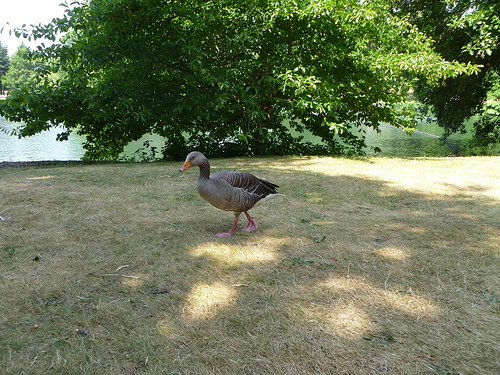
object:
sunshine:
[236, 155, 500, 201]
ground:
[0, 155, 499, 375]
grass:
[138, 218, 500, 375]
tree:
[0, 0, 499, 163]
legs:
[229, 215, 239, 233]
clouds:
[0, 4, 57, 21]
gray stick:
[379, 124, 456, 154]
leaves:
[310, 235, 327, 244]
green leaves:
[66, 0, 500, 163]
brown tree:
[0, 1, 485, 154]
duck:
[180, 151, 281, 238]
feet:
[215, 215, 238, 238]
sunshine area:
[281, 5, 500, 157]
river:
[0, 109, 500, 162]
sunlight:
[0, 104, 81, 163]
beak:
[178, 160, 191, 172]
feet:
[242, 211, 257, 232]